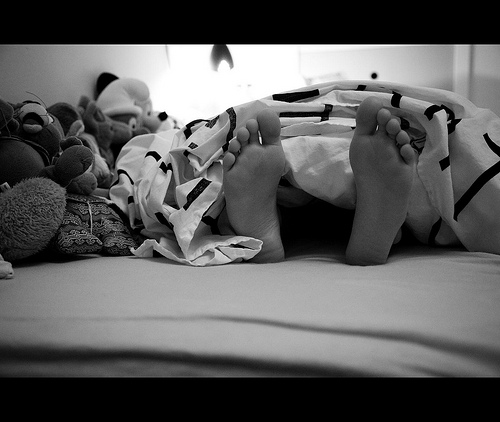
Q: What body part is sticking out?
A: Feet.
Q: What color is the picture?
A: Black and white.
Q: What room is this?
A: Bedroom.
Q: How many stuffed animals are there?
A: 3.